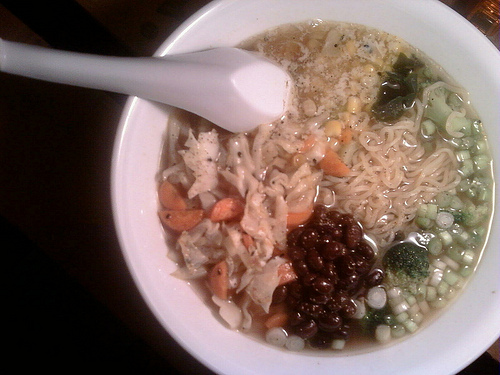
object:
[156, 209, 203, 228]
piece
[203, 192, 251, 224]
food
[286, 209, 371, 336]
beans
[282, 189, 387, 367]
food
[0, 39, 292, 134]
spoon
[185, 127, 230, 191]
seasoning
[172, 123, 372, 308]
vegetables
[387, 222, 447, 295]
broccoli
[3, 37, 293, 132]
utensil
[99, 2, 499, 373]
white bowl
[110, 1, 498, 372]
bowl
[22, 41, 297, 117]
white spoon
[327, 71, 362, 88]
fat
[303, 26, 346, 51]
broth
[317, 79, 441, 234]
noodles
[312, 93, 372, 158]
kernels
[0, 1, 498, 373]
table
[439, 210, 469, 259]
onions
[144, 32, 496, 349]
food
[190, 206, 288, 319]
chicken